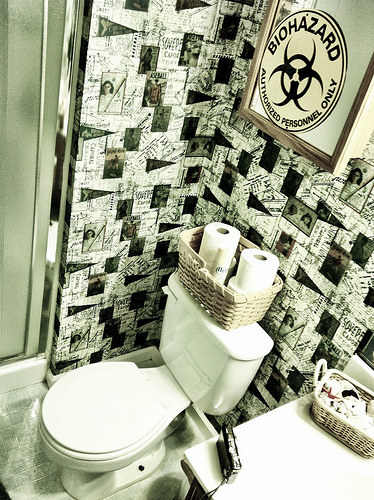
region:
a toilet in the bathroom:
[4, 6, 370, 498]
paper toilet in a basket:
[165, 216, 295, 330]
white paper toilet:
[193, 218, 277, 302]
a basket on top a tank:
[154, 213, 281, 429]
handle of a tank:
[151, 275, 181, 310]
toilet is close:
[21, 348, 189, 498]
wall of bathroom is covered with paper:
[74, 5, 372, 409]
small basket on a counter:
[290, 355, 372, 466]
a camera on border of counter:
[180, 413, 255, 498]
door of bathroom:
[1, 5, 93, 386]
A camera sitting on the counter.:
[198, 422, 241, 497]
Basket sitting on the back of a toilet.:
[178, 223, 282, 331]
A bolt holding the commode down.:
[138, 464, 143, 471]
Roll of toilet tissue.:
[234, 248, 278, 292]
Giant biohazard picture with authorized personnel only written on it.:
[257, 9, 348, 134]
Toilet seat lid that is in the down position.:
[40, 359, 166, 454]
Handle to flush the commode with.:
[161, 286, 176, 304]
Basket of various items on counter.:
[307, 358, 372, 458]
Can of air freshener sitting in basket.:
[211, 245, 232, 282]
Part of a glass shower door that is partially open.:
[1, 1, 83, 363]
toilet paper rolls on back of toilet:
[202, 223, 278, 303]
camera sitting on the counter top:
[215, 422, 240, 485]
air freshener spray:
[213, 247, 230, 283]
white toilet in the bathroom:
[41, 276, 269, 497]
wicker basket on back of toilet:
[178, 228, 282, 327]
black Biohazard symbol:
[269, 26, 324, 112]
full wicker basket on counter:
[317, 354, 370, 457]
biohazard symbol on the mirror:
[258, 9, 348, 132]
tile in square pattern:
[1, 380, 65, 498]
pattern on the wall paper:
[73, 0, 366, 423]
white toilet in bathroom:
[39, 274, 243, 442]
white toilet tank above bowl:
[163, 288, 263, 400]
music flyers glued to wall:
[108, 159, 286, 234]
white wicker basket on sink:
[296, 383, 372, 444]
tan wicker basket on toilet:
[171, 245, 289, 332]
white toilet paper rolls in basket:
[204, 229, 279, 284]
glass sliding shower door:
[4, 10, 67, 328]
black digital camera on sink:
[211, 415, 242, 476]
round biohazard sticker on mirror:
[255, 20, 337, 115]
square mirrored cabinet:
[246, 1, 373, 163]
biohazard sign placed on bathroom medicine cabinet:
[258, 8, 348, 128]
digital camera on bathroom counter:
[216, 421, 241, 483]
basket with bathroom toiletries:
[308, 356, 373, 459]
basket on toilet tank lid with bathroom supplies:
[176, 219, 283, 323]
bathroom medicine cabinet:
[234, 1, 371, 175]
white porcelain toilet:
[32, 269, 276, 498]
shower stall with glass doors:
[3, 0, 83, 368]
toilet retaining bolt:
[137, 463, 144, 471]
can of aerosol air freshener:
[211, 247, 230, 283]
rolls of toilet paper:
[199, 218, 279, 293]